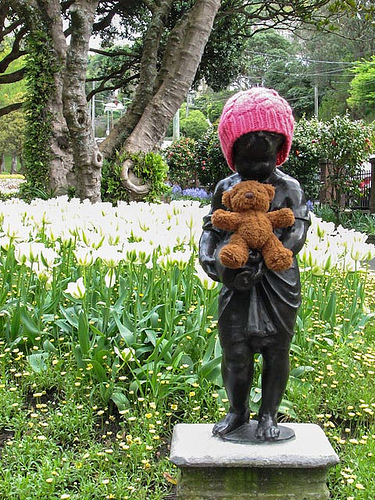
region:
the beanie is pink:
[213, 73, 299, 175]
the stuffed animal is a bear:
[213, 177, 307, 282]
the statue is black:
[185, 97, 309, 458]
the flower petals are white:
[3, 187, 193, 275]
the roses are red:
[310, 104, 372, 240]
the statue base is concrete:
[167, 411, 337, 498]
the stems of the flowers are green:
[11, 267, 212, 350]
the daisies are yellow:
[10, 352, 162, 480]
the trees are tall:
[17, 3, 220, 217]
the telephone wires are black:
[240, 41, 371, 103]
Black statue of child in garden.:
[189, 86, 317, 450]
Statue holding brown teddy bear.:
[213, 180, 292, 287]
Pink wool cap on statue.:
[212, 87, 298, 171]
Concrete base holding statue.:
[166, 421, 343, 497]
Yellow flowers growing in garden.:
[28, 407, 152, 499]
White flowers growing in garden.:
[29, 201, 170, 298]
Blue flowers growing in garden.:
[164, 181, 210, 202]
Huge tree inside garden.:
[13, 5, 242, 196]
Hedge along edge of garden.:
[170, 136, 226, 190]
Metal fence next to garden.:
[315, 157, 373, 214]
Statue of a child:
[197, 88, 300, 446]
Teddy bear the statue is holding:
[213, 176, 297, 274]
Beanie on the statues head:
[215, 84, 296, 174]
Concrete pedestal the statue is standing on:
[169, 419, 341, 498]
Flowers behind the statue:
[1, 195, 372, 281]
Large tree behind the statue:
[11, 0, 222, 203]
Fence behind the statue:
[315, 158, 373, 211]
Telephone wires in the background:
[234, 42, 369, 114]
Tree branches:
[217, 0, 368, 40]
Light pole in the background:
[90, 73, 101, 139]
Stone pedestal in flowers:
[164, 409, 352, 488]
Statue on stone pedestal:
[208, 98, 303, 435]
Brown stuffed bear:
[200, 181, 304, 272]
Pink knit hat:
[226, 82, 283, 178]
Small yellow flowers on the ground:
[52, 366, 150, 463]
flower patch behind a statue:
[5, 198, 211, 300]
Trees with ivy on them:
[16, 30, 178, 204]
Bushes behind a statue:
[171, 133, 371, 208]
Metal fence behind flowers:
[312, 165, 372, 213]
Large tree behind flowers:
[133, 12, 218, 212]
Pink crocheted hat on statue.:
[216, 90, 298, 178]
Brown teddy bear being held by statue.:
[212, 179, 307, 276]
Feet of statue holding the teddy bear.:
[210, 400, 298, 455]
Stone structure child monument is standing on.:
[180, 426, 342, 497]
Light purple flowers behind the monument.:
[172, 180, 212, 201]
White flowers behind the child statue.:
[4, 191, 359, 311]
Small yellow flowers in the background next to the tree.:
[1, 171, 25, 179]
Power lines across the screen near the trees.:
[113, 44, 371, 90]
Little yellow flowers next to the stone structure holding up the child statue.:
[4, 394, 372, 490]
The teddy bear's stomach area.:
[237, 206, 274, 247]